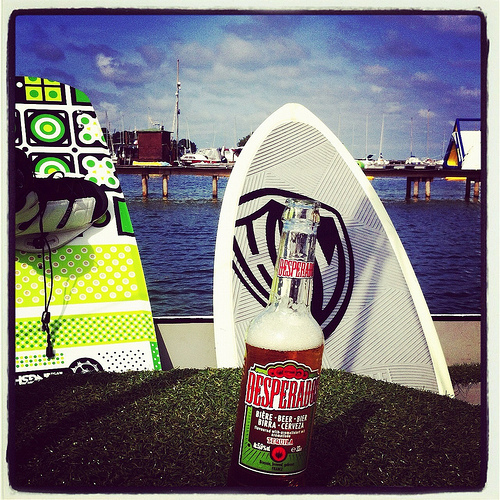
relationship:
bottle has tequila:
[213, 190, 326, 487] [226, 337, 325, 487]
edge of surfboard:
[225, 99, 318, 120] [199, 88, 462, 404]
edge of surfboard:
[18, 70, 87, 95] [13, 65, 162, 372]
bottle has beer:
[213, 190, 326, 487] [226, 337, 325, 487]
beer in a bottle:
[226, 337, 325, 487] [213, 190, 326, 487]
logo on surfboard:
[226, 186, 358, 357] [199, 88, 462, 404]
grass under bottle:
[11, 362, 491, 493] [213, 190, 326, 487]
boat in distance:
[179, 149, 228, 169] [17, 10, 491, 213]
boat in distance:
[102, 112, 124, 167] [17, 10, 491, 213]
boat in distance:
[131, 156, 178, 168] [17, 10, 491, 213]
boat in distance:
[360, 110, 398, 172] [17, 10, 491, 213]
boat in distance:
[398, 117, 430, 172] [17, 10, 491, 213]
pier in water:
[105, 158, 480, 210] [107, 164, 480, 321]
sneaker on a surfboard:
[12, 143, 110, 237] [13, 65, 162, 372]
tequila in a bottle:
[226, 337, 325, 487] [213, 190, 326, 487]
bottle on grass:
[213, 190, 326, 487] [11, 362, 491, 493]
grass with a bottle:
[11, 362, 491, 493] [213, 190, 326, 487]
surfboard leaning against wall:
[199, 88, 462, 404] [144, 310, 486, 414]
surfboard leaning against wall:
[13, 65, 162, 372] [144, 310, 486, 414]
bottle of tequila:
[213, 190, 326, 487] [226, 337, 325, 487]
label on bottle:
[241, 368, 319, 413] [213, 190, 326, 487]